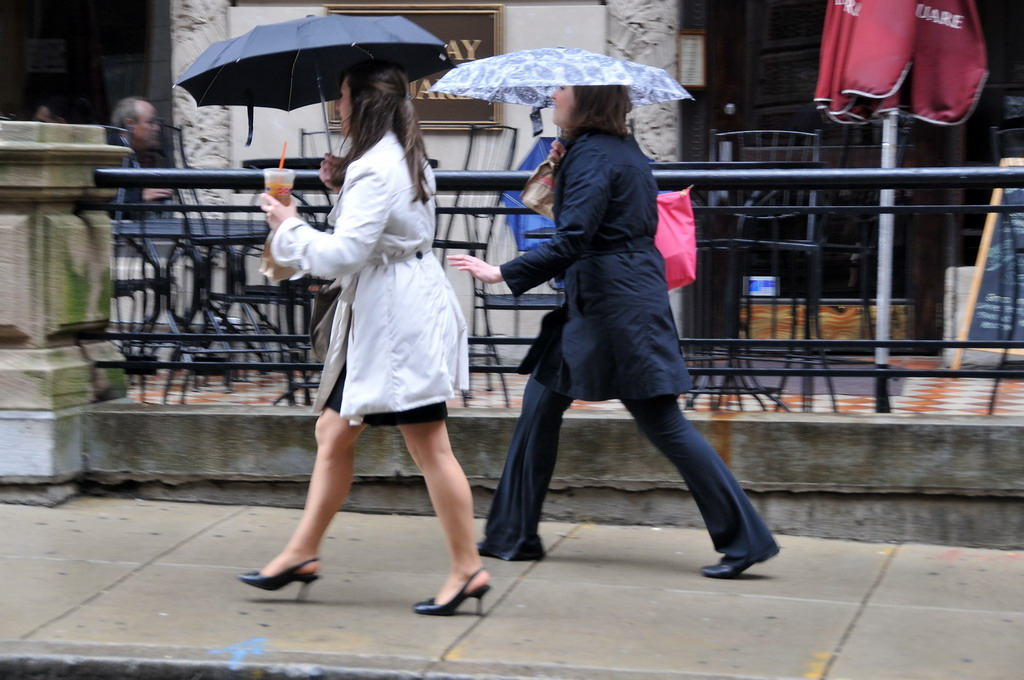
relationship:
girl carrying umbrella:
[234, 67, 494, 618] [166, 23, 415, 97]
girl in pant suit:
[445, 70, 780, 580] [486, 120, 716, 594]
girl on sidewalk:
[234, 67, 494, 618] [21, 443, 951, 675]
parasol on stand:
[814, 10, 970, 117] [857, 123, 927, 419]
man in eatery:
[66, 77, 211, 302] [40, 12, 1021, 665]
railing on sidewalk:
[94, 153, 1013, 212] [49, 360, 1013, 667]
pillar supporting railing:
[157, 4, 278, 326] [40, 136, 1021, 257]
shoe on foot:
[229, 548, 353, 616] [222, 544, 326, 601]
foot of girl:
[222, 544, 326, 601] [229, 39, 472, 537]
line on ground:
[807, 617, 847, 672] [8, 445, 1022, 660]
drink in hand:
[246, 164, 292, 223] [239, 190, 289, 253]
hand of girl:
[239, 190, 289, 253] [257, 103, 476, 611]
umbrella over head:
[185, 17, 466, 85] [323, 49, 408, 183]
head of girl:
[323, 49, 408, 183] [283, 26, 471, 634]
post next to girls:
[2, 129, 111, 305] [291, 79, 648, 481]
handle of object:
[311, 116, 353, 209] [144, 17, 432, 359]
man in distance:
[89, 95, 182, 238] [30, 32, 929, 368]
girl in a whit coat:
[234, 67, 494, 618] [265, 115, 482, 424]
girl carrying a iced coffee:
[234, 67, 494, 618] [239, 132, 311, 225]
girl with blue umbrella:
[460, 91, 849, 612] [412, 31, 752, 98]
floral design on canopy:
[469, 42, 616, 77] [453, 44, 685, 96]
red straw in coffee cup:
[268, 134, 305, 176] [263, 167, 303, 219]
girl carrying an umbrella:
[234, 67, 494, 618] [172, 16, 454, 110]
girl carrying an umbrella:
[445, 70, 780, 580] [402, 46, 705, 116]